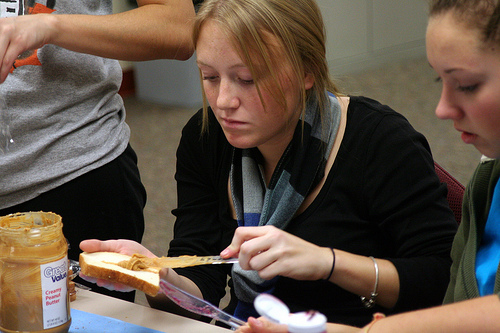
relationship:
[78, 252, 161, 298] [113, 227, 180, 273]
bread slices with butter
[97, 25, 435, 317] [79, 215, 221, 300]
girl making sandwich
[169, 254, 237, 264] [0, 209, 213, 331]
knife with butter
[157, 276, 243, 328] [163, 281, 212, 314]
knife with jam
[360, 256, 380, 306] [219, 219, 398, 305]
bracelet on arm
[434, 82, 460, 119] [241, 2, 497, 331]
nose of lady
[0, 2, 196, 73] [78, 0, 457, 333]
arm beside girl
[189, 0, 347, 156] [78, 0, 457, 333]
girl hair of a girl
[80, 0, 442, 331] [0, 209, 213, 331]
woman looks down at butter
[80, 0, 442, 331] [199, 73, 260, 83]
woman has eyelashes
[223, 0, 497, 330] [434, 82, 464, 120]
woman has nose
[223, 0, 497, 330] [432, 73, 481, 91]
woman has eyelashes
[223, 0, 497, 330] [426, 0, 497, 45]
woman has hair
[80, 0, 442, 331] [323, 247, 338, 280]
woman wears black bracelet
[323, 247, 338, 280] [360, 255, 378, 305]
black bracelet wears bracelet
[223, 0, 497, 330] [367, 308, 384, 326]
woman wears bracelet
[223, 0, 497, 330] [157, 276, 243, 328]
woman holds knife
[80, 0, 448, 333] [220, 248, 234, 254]
woman have fingernails